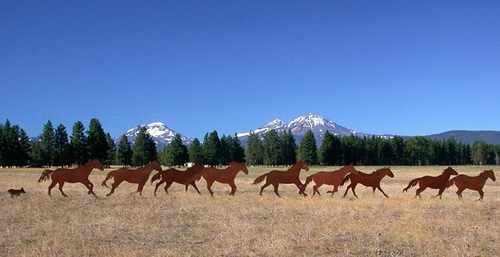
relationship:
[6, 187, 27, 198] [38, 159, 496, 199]
dog behind horses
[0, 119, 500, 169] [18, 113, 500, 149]
trees in front of mountains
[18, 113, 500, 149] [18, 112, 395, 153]
mountains are covered with snow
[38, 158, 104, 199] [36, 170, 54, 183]
horse has a tail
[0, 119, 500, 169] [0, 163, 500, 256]
trees on grass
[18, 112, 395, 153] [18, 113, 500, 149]
snow on mountains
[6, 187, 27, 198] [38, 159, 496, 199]
dog chasing horses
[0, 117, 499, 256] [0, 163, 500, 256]
field has grass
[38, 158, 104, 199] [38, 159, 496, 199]
horse in back of or horses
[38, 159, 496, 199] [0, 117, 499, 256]
horses are running on field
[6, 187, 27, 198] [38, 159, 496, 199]
dog running behind horses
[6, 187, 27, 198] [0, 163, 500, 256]
dog running on grass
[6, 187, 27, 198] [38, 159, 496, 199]
dog and horses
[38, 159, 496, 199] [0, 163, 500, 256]
horses on grass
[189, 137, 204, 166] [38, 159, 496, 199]
tree behind horses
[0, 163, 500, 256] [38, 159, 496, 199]
grass near horses